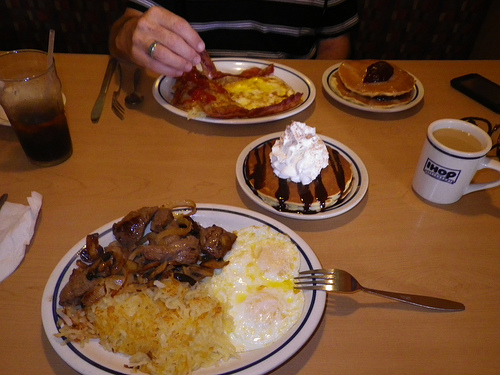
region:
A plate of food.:
[39, 201, 328, 373]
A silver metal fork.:
[293, 267, 466, 314]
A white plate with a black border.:
[38, 201, 328, 373]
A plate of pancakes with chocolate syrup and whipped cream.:
[233, 119, 369, 221]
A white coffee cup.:
[409, 118, 499, 205]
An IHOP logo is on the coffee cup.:
[420, 155, 460, 187]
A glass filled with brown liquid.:
[2, 47, 74, 170]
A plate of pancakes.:
[320, 58, 424, 115]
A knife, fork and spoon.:
[90, 55, 143, 122]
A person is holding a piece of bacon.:
[106, 0, 359, 80]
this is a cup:
[418, 114, 489, 215]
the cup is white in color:
[419, 141, 461, 159]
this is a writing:
[410, 159, 459, 182]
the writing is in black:
[427, 156, 444, 179]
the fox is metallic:
[322, 263, 365, 288]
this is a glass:
[13, 58, 93, 136]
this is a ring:
[141, 39, 165, 59]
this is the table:
[71, 127, 198, 187]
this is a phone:
[458, 67, 498, 113]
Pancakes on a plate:
[236, 123, 363, 216]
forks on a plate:
[296, 263, 478, 326]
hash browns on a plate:
[97, 282, 229, 357]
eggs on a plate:
[222, 233, 306, 335]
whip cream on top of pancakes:
[273, 124, 321, 181]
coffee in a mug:
[420, 108, 496, 216]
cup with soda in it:
[7, 54, 80, 180]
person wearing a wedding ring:
[143, 40, 164, 67]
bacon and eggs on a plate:
[183, 51, 306, 131]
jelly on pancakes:
[363, 63, 398, 86]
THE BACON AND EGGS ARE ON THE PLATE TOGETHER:
[156, 52, 318, 117]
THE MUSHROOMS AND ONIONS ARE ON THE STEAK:
[57, 205, 232, 296]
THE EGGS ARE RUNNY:
[213, 222, 314, 362]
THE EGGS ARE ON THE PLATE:
[207, 221, 308, 348]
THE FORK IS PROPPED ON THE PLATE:
[291, 262, 464, 335]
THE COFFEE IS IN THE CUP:
[405, 118, 496, 229]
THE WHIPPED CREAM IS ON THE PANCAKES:
[230, 113, 371, 228]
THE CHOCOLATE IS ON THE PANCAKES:
[228, 116, 381, 254]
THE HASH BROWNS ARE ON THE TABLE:
[67, 282, 232, 372]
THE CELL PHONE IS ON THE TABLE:
[442, 68, 499, 123]